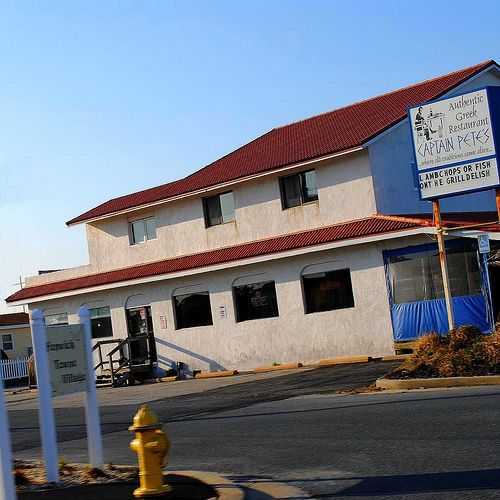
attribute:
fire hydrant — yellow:
[128, 403, 175, 497]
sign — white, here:
[408, 84, 500, 202]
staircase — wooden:
[90, 332, 155, 387]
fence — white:
[0, 353, 35, 380]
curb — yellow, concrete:
[375, 375, 500, 391]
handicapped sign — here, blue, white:
[157, 315, 169, 329]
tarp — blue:
[381, 235, 496, 343]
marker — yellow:
[193, 371, 240, 378]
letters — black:
[417, 161, 494, 190]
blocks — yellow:
[135, 354, 407, 386]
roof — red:
[64, 61, 493, 228]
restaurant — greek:
[7, 60, 499, 374]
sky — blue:
[1, 0, 498, 305]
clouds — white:
[3, 193, 98, 314]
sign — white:
[42, 323, 93, 397]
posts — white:
[30, 307, 105, 483]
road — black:
[2, 386, 499, 498]